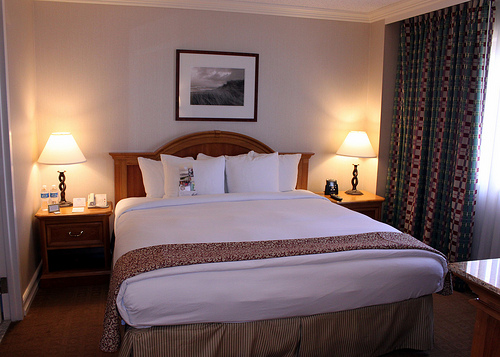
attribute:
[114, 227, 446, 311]
strip — brown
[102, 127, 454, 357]
bed — brown, white, foreground, made, striped, mattress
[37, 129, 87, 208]
lamp — small, lit, white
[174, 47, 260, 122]
picture — white, mountains, frame, hanging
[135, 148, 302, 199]
pillows — white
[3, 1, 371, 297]
wall — white, clean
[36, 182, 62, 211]
bottles — water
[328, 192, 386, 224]
table — wooden, edge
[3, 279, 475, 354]
carpet — brown, floor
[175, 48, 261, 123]
photo — small